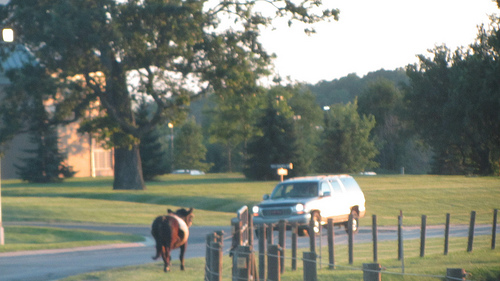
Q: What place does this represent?
A: It represents the forest.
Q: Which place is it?
A: It is a forest.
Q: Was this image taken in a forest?
A: Yes, it was taken in a forest.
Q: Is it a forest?
A: Yes, it is a forest.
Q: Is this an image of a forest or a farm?
A: It is showing a forest.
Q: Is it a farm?
A: No, it is a forest.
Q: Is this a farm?
A: No, it is a forest.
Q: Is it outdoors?
A: Yes, it is outdoors.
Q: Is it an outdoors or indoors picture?
A: It is outdoors.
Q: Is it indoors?
A: No, it is outdoors.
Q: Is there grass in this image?
A: Yes, there is grass.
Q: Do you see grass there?
A: Yes, there is grass.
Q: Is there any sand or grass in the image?
A: Yes, there is grass.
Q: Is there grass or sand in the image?
A: Yes, there is grass.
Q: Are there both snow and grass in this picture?
A: No, there is grass but no snow.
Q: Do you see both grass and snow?
A: No, there is grass but no snow.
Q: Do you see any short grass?
A: Yes, there is short grass.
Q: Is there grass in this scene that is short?
A: Yes, there is grass that is short.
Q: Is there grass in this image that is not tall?
A: Yes, there is short grass.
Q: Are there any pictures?
A: No, there are no pictures.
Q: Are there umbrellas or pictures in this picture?
A: No, there are no pictures or umbrellas.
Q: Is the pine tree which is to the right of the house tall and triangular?
A: Yes, the pine tree is tall and triangular.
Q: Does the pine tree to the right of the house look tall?
A: Yes, the pine tree is tall.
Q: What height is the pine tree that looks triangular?
A: The pine is tall.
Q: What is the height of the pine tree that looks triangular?
A: The pine is tall.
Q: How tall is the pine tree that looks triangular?
A: The pine is tall.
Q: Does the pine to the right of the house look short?
A: No, the pine is tall.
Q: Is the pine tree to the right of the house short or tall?
A: The pine tree is tall.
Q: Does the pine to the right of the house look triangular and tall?
A: Yes, the pine is triangular and tall.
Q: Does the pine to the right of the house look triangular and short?
A: No, the pine is triangular but tall.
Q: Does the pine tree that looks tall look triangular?
A: Yes, the pine tree is triangular.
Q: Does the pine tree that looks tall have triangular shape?
A: Yes, the pine tree is triangular.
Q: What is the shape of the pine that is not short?
A: The pine is triangular.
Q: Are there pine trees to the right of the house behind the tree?
A: Yes, there is a pine tree to the right of the house.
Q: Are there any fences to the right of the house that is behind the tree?
A: No, there is a pine tree to the right of the house.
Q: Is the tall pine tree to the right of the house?
A: Yes, the pine tree is to the right of the house.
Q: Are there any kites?
A: No, there are no kites.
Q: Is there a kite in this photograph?
A: No, there are no kites.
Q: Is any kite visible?
A: No, there are no kites.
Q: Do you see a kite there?
A: No, there are no kites.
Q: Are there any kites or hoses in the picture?
A: No, there are no kites or hoses.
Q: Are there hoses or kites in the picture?
A: No, there are no kites or hoses.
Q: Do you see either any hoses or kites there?
A: No, there are no kites or hoses.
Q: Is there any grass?
A: Yes, there is grass.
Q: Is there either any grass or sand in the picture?
A: Yes, there is grass.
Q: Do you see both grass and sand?
A: No, there is grass but no sand.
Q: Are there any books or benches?
A: No, there are no benches or books.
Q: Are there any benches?
A: No, there are no benches.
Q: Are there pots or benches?
A: No, there are no benches or pots.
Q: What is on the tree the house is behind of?
A: The trunk is on the tree.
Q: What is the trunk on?
A: The trunk is on the tree.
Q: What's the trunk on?
A: The trunk is on the tree.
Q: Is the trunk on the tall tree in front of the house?
A: Yes, the trunk is on the tree.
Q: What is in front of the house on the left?
A: The tree is in front of the house.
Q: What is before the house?
A: The tree is in front of the house.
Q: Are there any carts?
A: No, there are no carts.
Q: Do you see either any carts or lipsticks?
A: No, there are no carts or lipsticks.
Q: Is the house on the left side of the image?
A: Yes, the house is on the left of the image.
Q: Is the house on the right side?
A: No, the house is on the left of the image.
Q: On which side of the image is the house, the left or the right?
A: The house is on the left of the image.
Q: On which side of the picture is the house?
A: The house is on the left of the image.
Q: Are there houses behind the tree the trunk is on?
A: Yes, there is a house behind the tree.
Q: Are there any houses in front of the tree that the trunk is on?
A: No, the house is behind the tree.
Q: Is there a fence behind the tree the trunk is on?
A: No, there is a house behind the tree.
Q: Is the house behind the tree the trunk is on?
A: Yes, the house is behind the tree.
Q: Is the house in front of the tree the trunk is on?
A: No, the house is behind the tree.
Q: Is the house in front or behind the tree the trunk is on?
A: The house is behind the tree.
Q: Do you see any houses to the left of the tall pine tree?
A: Yes, there is a house to the left of the pine tree.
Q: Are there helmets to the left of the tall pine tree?
A: No, there is a house to the left of the pine tree.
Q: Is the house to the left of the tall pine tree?
A: Yes, the house is to the left of the pine tree.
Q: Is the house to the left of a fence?
A: No, the house is to the left of the pine tree.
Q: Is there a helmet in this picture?
A: No, there are no helmets.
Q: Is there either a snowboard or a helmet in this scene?
A: No, there are no helmets or snowboards.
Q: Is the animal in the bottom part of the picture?
A: Yes, the animal is in the bottom of the image.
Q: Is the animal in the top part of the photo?
A: No, the animal is in the bottom of the image.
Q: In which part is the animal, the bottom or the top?
A: The animal is in the bottom of the image.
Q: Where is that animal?
A: The animal is on the grass.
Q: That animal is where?
A: The animal is on the grass.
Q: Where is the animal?
A: The animal is on the grass.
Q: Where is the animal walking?
A: The animal is walking on the road.